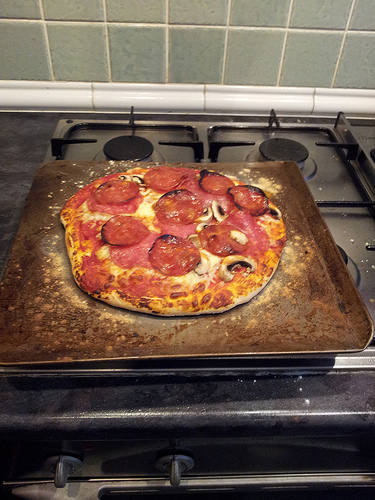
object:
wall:
[0, 0, 374, 117]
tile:
[1, 18, 56, 86]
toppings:
[87, 162, 270, 287]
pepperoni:
[146, 233, 201, 280]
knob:
[155, 454, 192, 486]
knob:
[46, 455, 84, 491]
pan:
[0, 160, 374, 375]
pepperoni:
[226, 184, 271, 217]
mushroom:
[218, 254, 255, 285]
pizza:
[56, 159, 291, 321]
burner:
[207, 108, 374, 213]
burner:
[48, 96, 208, 164]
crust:
[59, 162, 286, 320]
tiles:
[41, 15, 114, 96]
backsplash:
[0, 0, 374, 124]